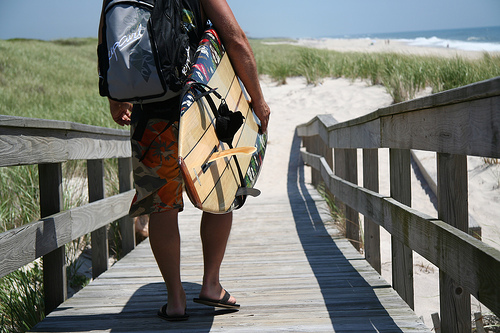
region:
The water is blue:
[313, 23, 498, 67]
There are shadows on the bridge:
[269, 114, 431, 331]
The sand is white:
[275, 36, 441, 91]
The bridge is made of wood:
[266, 105, 496, 322]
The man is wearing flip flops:
[136, 260, 266, 330]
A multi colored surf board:
[153, 12, 324, 262]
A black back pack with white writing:
[82, 5, 177, 116]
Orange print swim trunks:
[90, 97, 226, 260]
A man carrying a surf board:
[55, 8, 323, 309]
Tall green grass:
[265, 30, 431, 90]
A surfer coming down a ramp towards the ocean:
[90, 0, 282, 321]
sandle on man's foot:
[198, 285, 240, 310]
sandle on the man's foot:
[149, 291, 191, 323]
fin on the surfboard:
[199, 136, 254, 164]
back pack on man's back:
[98, 4, 170, 101]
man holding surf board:
[84, 3, 287, 320]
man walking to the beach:
[96, 2, 282, 318]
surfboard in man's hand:
[179, 22, 276, 217]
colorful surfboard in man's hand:
[175, 23, 275, 217]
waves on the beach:
[391, 29, 497, 56]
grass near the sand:
[297, 57, 326, 84]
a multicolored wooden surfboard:
[169, 22, 270, 212]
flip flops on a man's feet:
[155, 291, 244, 318]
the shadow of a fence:
[281, 129, 399, 331]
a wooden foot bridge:
[1, 73, 497, 330]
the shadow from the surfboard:
[117, 272, 213, 331]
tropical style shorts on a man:
[112, 103, 213, 220]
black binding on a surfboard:
[197, 80, 259, 192]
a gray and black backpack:
[100, 0, 190, 105]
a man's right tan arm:
[207, 0, 273, 133]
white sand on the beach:
[255, 72, 497, 325]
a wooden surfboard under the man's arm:
[175, 28, 267, 213]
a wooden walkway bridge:
[1, 75, 498, 331]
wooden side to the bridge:
[292, 77, 498, 332]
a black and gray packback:
[97, 0, 189, 106]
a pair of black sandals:
[154, 291, 241, 323]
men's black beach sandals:
[155, 288, 242, 323]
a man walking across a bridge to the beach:
[95, 0, 270, 330]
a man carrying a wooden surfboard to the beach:
[1, 1, 498, 331]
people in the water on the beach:
[345, 27, 499, 50]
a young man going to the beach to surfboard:
[95, 2, 270, 323]